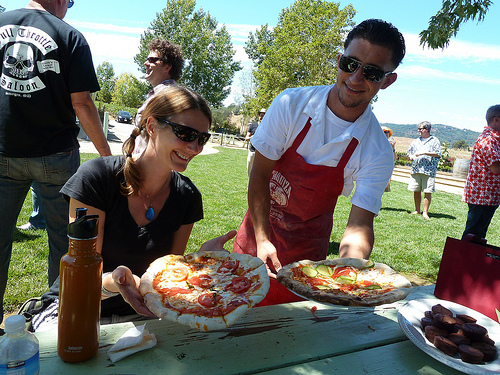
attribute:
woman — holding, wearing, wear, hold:
[82, 69, 228, 337]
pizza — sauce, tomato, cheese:
[185, 243, 246, 307]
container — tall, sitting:
[46, 190, 123, 359]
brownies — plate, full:
[417, 292, 494, 367]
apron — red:
[241, 149, 339, 240]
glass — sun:
[160, 121, 212, 149]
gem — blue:
[133, 196, 158, 234]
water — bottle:
[1, 318, 47, 371]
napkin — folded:
[122, 320, 150, 349]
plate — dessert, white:
[393, 293, 475, 373]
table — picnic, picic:
[239, 300, 384, 371]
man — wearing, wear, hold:
[230, 77, 415, 262]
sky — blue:
[226, 14, 265, 38]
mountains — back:
[415, 120, 463, 144]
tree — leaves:
[261, 22, 326, 92]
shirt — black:
[6, 27, 60, 103]